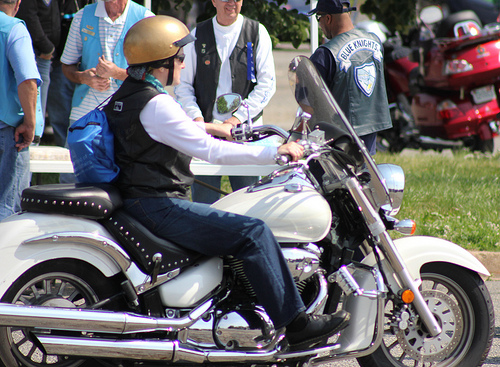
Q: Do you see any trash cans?
A: No, there are no trash cans.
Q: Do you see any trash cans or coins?
A: No, there are no trash cans or coins.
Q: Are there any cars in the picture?
A: No, there are no cars.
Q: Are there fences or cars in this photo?
A: No, there are no cars or fences.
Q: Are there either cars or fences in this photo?
A: No, there are no cars or fences.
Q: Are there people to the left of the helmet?
A: Yes, there are people to the left of the helmet.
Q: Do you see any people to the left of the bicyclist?
A: Yes, there are people to the left of the bicyclist.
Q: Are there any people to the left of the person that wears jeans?
A: Yes, there are people to the left of the bicyclist.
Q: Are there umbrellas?
A: No, there are no umbrellas.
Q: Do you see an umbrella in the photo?
A: No, there are no umbrellas.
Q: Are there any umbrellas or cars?
A: No, there are no umbrellas or cars.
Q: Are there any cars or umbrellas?
A: No, there are no umbrellas or cars.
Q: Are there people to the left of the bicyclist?
A: Yes, there are people to the left of the bicyclist.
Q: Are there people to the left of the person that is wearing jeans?
A: Yes, there are people to the left of the bicyclist.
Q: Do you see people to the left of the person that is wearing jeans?
A: Yes, there are people to the left of the bicyclist.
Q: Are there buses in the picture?
A: No, there are no buses.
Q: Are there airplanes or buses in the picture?
A: No, there are no buses or airplanes.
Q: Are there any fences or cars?
A: No, there are no cars or fences.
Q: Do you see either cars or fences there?
A: No, there are no cars or fences.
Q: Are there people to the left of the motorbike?
A: Yes, there are people to the left of the motorbike.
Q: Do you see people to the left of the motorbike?
A: Yes, there are people to the left of the motorbike.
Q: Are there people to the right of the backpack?
A: Yes, there are people to the right of the backpack.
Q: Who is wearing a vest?
A: The people are wearing a vest.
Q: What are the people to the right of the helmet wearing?
A: The people are wearing a vest.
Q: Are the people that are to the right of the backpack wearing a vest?
A: Yes, the people are wearing a vest.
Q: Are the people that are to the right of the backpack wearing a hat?
A: No, the people are wearing a vest.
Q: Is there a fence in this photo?
A: No, there are no fences.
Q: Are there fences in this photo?
A: No, there are no fences.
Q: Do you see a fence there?
A: No, there are no fences.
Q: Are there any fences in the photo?
A: No, there are no fences.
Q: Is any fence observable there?
A: No, there are no fences.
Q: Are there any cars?
A: No, there are no cars.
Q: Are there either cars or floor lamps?
A: No, there are no cars or floor lamps.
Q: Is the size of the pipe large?
A: Yes, the pipe is large.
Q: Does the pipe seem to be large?
A: Yes, the pipe is large.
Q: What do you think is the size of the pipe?
A: The pipe is large.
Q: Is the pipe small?
A: No, the pipe is large.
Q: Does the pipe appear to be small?
A: No, the pipe is large.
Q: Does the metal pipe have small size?
A: No, the pipe is large.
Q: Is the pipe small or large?
A: The pipe is large.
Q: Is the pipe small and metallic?
A: No, the pipe is metallic but large.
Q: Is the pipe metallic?
A: Yes, the pipe is metallic.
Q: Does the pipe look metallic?
A: Yes, the pipe is metallic.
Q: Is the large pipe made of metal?
A: Yes, the pipe is made of metal.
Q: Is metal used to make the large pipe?
A: Yes, the pipe is made of metal.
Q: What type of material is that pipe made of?
A: The pipe is made of metal.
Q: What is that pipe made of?
A: The pipe is made of metal.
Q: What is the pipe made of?
A: The pipe is made of metal.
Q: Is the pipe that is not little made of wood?
A: No, the pipe is made of metal.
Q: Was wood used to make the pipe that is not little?
A: No, the pipe is made of metal.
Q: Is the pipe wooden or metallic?
A: The pipe is metallic.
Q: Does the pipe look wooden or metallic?
A: The pipe is metallic.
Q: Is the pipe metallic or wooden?
A: The pipe is metallic.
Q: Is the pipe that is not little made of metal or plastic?
A: The pipe is made of metal.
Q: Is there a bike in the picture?
A: Yes, there is a bike.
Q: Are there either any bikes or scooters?
A: Yes, there is a bike.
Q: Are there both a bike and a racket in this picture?
A: No, there is a bike but no rackets.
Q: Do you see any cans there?
A: No, there are no cans.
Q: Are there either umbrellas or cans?
A: No, there are no cans or umbrellas.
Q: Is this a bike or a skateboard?
A: This is a bike.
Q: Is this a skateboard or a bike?
A: This is a bike.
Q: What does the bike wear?
A: The bike wears jeans.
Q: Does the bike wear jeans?
A: Yes, the bike wears jeans.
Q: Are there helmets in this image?
A: Yes, there is a helmet.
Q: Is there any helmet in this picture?
A: Yes, there is a helmet.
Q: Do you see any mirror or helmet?
A: Yes, there is a helmet.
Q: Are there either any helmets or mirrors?
A: Yes, there is a helmet.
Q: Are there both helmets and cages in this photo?
A: No, there is a helmet but no cages.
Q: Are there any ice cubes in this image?
A: No, there are no ice cubes.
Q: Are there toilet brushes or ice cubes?
A: No, there are no ice cubes or toilet brushes.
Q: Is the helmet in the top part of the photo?
A: Yes, the helmet is in the top of the image.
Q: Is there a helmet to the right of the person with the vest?
A: Yes, there is a helmet to the right of the person.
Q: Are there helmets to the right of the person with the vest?
A: Yes, there is a helmet to the right of the person.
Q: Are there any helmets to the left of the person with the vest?
A: No, the helmet is to the right of the person.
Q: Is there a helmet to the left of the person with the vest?
A: No, the helmet is to the right of the person.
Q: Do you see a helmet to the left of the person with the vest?
A: No, the helmet is to the right of the person.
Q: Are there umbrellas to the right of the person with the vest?
A: No, there is a helmet to the right of the person.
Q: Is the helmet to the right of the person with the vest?
A: Yes, the helmet is to the right of the person.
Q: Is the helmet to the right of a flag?
A: No, the helmet is to the right of the person.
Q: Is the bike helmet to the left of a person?
A: No, the helmet is to the right of a person.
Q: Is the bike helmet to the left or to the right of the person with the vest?
A: The helmet is to the right of the person.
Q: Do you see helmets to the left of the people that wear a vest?
A: Yes, there is a helmet to the left of the people.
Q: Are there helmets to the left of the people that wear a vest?
A: Yes, there is a helmet to the left of the people.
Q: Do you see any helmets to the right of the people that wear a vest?
A: No, the helmet is to the left of the people.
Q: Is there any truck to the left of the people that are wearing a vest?
A: No, there is a helmet to the left of the people.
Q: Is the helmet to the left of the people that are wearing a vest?
A: Yes, the helmet is to the left of the people.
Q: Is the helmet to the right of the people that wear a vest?
A: No, the helmet is to the left of the people.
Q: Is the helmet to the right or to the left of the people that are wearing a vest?
A: The helmet is to the left of the people.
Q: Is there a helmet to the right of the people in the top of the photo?
A: Yes, there is a helmet to the right of the people.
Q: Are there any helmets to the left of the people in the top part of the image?
A: No, the helmet is to the right of the people.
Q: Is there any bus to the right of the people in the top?
A: No, there is a helmet to the right of the people.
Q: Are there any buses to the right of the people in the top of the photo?
A: No, there is a helmet to the right of the people.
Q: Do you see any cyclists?
A: Yes, there is a cyclist.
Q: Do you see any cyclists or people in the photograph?
A: Yes, there is a cyclist.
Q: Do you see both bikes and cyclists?
A: Yes, there are both a cyclist and a bike.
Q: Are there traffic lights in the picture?
A: No, there are no traffic lights.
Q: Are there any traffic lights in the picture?
A: No, there are no traffic lights.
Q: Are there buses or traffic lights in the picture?
A: No, there are no traffic lights or buses.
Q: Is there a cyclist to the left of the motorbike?
A: Yes, there is a cyclist to the left of the motorbike.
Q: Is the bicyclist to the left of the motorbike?
A: Yes, the bicyclist is to the left of the motorbike.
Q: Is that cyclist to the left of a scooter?
A: No, the cyclist is to the left of the motorbike.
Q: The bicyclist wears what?
A: The bicyclist wears jeans.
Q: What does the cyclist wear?
A: The bicyclist wears jeans.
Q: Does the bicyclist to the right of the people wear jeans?
A: Yes, the bicyclist wears jeans.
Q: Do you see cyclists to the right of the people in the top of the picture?
A: Yes, there is a cyclist to the right of the people.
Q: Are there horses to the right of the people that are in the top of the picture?
A: No, there is a cyclist to the right of the people.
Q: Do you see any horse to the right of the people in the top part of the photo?
A: No, there is a cyclist to the right of the people.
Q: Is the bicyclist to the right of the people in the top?
A: Yes, the bicyclist is to the right of the people.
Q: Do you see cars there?
A: No, there are no cars.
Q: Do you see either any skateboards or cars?
A: No, there are no cars or skateboards.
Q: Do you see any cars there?
A: No, there are no cars.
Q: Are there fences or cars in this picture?
A: No, there are no cars or fences.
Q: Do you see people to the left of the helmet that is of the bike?
A: Yes, there is a person to the left of the helmet.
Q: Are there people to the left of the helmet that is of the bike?
A: Yes, there is a person to the left of the helmet.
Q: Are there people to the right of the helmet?
A: No, the person is to the left of the helmet.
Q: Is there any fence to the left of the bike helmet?
A: No, there is a person to the left of the helmet.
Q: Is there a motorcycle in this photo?
A: Yes, there is a motorcycle.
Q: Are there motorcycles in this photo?
A: Yes, there is a motorcycle.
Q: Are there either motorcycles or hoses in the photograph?
A: Yes, there is a motorcycle.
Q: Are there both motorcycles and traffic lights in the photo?
A: No, there is a motorcycle but no traffic lights.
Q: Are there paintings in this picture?
A: No, there are no paintings.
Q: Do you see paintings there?
A: No, there are no paintings.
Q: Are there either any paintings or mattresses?
A: No, there are no paintings or mattresses.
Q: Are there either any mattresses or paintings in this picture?
A: No, there are no paintings or mattresses.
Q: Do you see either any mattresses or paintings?
A: No, there are no paintings or mattresses.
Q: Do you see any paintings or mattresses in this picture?
A: No, there are no paintings or mattresses.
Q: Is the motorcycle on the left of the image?
A: No, the motorcycle is on the right of the image.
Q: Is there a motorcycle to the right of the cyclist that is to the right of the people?
A: Yes, there is a motorcycle to the right of the cyclist.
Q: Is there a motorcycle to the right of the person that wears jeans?
A: Yes, there is a motorcycle to the right of the cyclist.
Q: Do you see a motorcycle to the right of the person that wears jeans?
A: Yes, there is a motorcycle to the right of the cyclist.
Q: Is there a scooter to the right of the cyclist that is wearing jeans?
A: No, there is a motorcycle to the right of the bicyclist.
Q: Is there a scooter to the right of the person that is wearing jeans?
A: No, there is a motorcycle to the right of the bicyclist.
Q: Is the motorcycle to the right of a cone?
A: No, the motorcycle is to the right of the bicyclist.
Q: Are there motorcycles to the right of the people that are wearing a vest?
A: Yes, there is a motorcycle to the right of the people.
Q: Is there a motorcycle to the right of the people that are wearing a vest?
A: Yes, there is a motorcycle to the right of the people.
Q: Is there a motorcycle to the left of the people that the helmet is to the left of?
A: No, the motorcycle is to the right of the people.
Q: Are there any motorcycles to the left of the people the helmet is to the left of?
A: No, the motorcycle is to the right of the people.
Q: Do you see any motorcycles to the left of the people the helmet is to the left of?
A: No, the motorcycle is to the right of the people.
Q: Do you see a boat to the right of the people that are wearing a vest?
A: No, there is a motorcycle to the right of the people.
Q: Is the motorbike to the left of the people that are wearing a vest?
A: No, the motorbike is to the right of the people.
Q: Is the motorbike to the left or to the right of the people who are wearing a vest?
A: The motorbike is to the right of the people.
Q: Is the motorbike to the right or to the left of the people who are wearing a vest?
A: The motorbike is to the right of the people.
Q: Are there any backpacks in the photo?
A: Yes, there is a backpack.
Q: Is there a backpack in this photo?
A: Yes, there is a backpack.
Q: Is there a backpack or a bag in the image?
A: Yes, there is a backpack.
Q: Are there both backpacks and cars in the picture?
A: No, there is a backpack but no cars.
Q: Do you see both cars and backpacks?
A: No, there is a backpack but no cars.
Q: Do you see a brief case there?
A: No, there are no briefcases.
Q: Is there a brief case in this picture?
A: No, there are no briefcases.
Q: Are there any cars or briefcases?
A: No, there are no briefcases or cars.